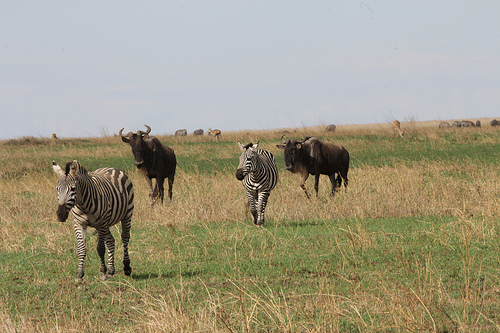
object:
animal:
[276, 133, 351, 199]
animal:
[119, 124, 177, 207]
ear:
[69, 159, 81, 174]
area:
[0, 121, 500, 333]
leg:
[257, 189, 269, 219]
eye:
[71, 187, 77, 191]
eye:
[56, 187, 58, 190]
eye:
[247, 157, 252, 161]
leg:
[98, 224, 115, 268]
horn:
[137, 124, 152, 136]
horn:
[119, 127, 134, 137]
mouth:
[56, 210, 69, 222]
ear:
[52, 160, 66, 179]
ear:
[252, 140, 260, 148]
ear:
[238, 140, 246, 151]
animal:
[235, 139, 280, 228]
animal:
[52, 159, 135, 285]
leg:
[246, 190, 257, 219]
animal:
[174, 129, 188, 137]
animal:
[193, 129, 204, 137]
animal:
[206, 127, 224, 143]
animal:
[325, 124, 336, 134]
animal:
[391, 120, 405, 139]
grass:
[0, 121, 499, 333]